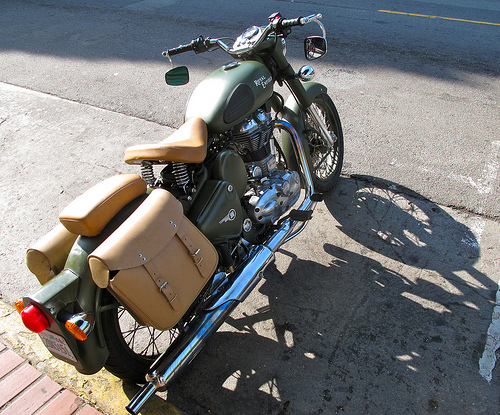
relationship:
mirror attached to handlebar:
[163, 62, 190, 85] [159, 36, 207, 58]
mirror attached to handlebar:
[292, 19, 337, 71] [140, 0, 335, 94]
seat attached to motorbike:
[121, 115, 211, 167] [13, 11, 345, 414]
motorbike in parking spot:
[13, 11, 345, 414] [3, 111, 498, 413]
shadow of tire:
[120, 172, 498, 415] [290, 93, 342, 200]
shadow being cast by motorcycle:
[239, 164, 483, 406] [29, 24, 386, 372]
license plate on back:
[27, 310, 82, 375] [17, 280, 109, 376]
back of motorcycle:
[17, 280, 109, 376] [34, 8, 417, 377]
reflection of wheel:
[331, 174, 475, 264] [294, 98, 355, 186]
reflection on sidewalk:
[331, 174, 475, 264] [242, 180, 483, 402]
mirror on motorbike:
[302, 19, 328, 62] [13, 11, 345, 414]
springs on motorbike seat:
[139, 158, 195, 187] [123, 116, 208, 166]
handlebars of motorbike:
[158, 9, 335, 88] [10, 9, 343, 411]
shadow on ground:
[165, 170, 498, 413] [279, 38, 485, 411]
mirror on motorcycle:
[160, 55, 189, 86] [36, 39, 337, 384]